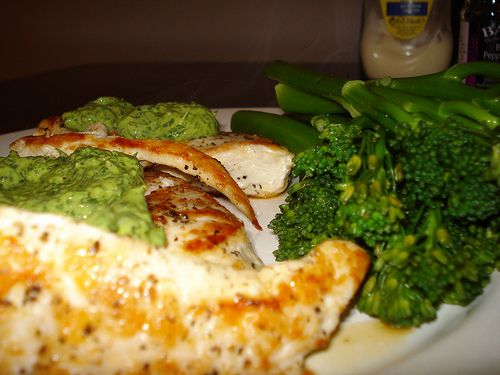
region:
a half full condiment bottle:
[360, 0, 456, 83]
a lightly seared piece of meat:
[1, 205, 369, 363]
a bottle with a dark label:
[451, 3, 498, 86]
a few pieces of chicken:
[146, 129, 363, 354]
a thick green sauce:
[0, 142, 164, 243]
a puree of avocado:
[1, 143, 160, 252]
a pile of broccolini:
[240, 58, 499, 309]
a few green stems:
[258, 59, 438, 134]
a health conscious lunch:
[1, 66, 491, 366]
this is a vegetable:
[230, 93, 314, 152]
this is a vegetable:
[300, 142, 340, 245]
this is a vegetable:
[324, 139, 409, 252]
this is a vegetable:
[339, 68, 429, 150]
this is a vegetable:
[432, 105, 464, 204]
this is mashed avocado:
[92, 187, 148, 225]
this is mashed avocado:
[41, 168, 130, 213]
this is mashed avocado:
[109, 100, 226, 139]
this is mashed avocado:
[50, 92, 138, 134]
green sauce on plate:
[15, 150, 115, 247]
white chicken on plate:
[164, 133, 306, 206]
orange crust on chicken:
[51, 134, 275, 200]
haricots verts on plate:
[260, 67, 453, 143]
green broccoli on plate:
[292, 126, 463, 318]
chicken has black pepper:
[160, 127, 272, 231]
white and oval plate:
[56, 102, 464, 349]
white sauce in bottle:
[328, 0, 430, 85]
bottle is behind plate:
[356, 0, 447, 82]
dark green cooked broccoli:
[292, 122, 469, 328]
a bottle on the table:
[355, 2, 446, 68]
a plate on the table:
[18, 97, 498, 372]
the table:
[71, 57, 298, 100]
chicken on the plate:
[7, 103, 377, 371]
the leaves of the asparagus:
[317, 132, 492, 322]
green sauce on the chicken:
[10, 150, 160, 241]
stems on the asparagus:
[233, 60, 475, 135]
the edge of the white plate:
[356, 313, 481, 365]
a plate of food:
[8, 70, 470, 323]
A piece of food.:
[338, 101, 408, 242]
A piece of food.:
[287, 145, 371, 257]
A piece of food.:
[392, 114, 481, 191]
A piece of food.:
[228, 97, 494, 321]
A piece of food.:
[24, 120, 292, 245]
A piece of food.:
[171, 125, 303, 201]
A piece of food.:
[114, 94, 224, 145]